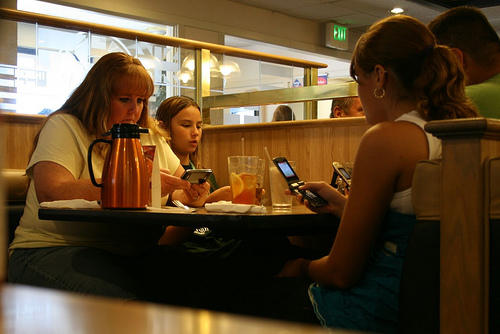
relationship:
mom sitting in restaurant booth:
[9, 51, 210, 309] [338, 107, 468, 331]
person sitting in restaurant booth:
[154, 94, 265, 282] [338, 107, 468, 331]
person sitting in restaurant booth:
[299, 16, 499, 333] [338, 107, 468, 331]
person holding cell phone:
[299, 16, 499, 333] [271, 157, 326, 210]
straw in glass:
[239, 133, 245, 173] [220, 129, 272, 209]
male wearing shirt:
[424, 8, 500, 122] [462, 74, 498, 119]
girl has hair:
[152, 93, 268, 203] [158, 85, 210, 182]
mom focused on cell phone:
[9, 51, 210, 309] [180, 167, 212, 182]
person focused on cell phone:
[299, 16, 499, 333] [271, 157, 326, 210]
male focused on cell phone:
[424, 8, 500, 122] [330, 161, 350, 186]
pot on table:
[83, 118, 159, 214] [36, 190, 346, 296]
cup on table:
[241, 154, 268, 206] [35, 196, 337, 236]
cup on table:
[227, 156, 266, 206] [35, 196, 337, 236]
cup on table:
[268, 154, 298, 203] [35, 196, 337, 236]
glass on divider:
[24, 30, 94, 80] [3, 4, 330, 127]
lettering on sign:
[332, 24, 347, 43] [325, 17, 350, 55]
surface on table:
[2, 282, 336, 332] [5, 262, 379, 328]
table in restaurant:
[66, 179, 357, 260] [0, 0, 498, 330]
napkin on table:
[205, 197, 266, 214] [43, 182, 348, 272]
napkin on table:
[38, 191, 103, 209] [43, 182, 348, 272]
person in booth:
[163, 94, 248, 202] [7, 117, 495, 332]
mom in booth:
[9, 51, 210, 309] [7, 117, 495, 332]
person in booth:
[299, 16, 479, 333] [7, 117, 495, 332]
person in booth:
[417, 6, 499, 113] [7, 117, 495, 332]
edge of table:
[37, 207, 319, 224] [37, 199, 335, 226]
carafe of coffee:
[89, 120, 163, 205] [78, 105, 180, 225]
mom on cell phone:
[9, 50, 207, 281] [171, 163, 226, 191]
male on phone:
[424, 4, 484, 117] [404, 2, 498, 144]